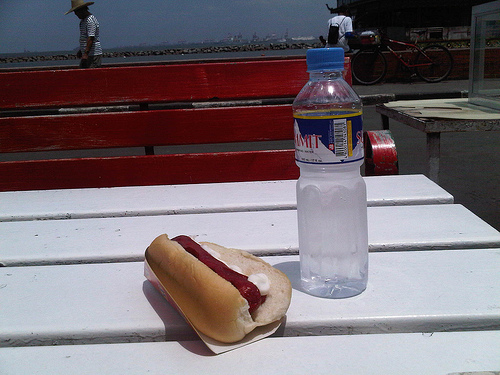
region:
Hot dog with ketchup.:
[140, 203, 300, 358]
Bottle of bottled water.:
[305, 39, 378, 346]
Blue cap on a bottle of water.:
[289, 36, 357, 71]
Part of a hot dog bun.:
[136, 245, 243, 371]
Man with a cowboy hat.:
[39, 0, 111, 70]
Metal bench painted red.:
[35, 50, 420, 233]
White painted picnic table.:
[12, 159, 480, 371]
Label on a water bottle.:
[279, 78, 374, 186]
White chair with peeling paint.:
[388, 7, 498, 188]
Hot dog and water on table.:
[176, 182, 389, 342]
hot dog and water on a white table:
[133, 8, 410, 371]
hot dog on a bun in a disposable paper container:
[117, 224, 297, 353]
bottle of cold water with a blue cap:
[290, 26, 383, 313]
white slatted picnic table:
[7, 188, 119, 373]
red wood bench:
[10, 72, 268, 182]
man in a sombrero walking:
[57, 1, 119, 71]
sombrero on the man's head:
[62, 0, 104, 19]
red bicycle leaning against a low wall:
[350, 16, 465, 86]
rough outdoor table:
[385, 86, 499, 173]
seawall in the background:
[138, 16, 308, 55]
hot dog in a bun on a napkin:
[115, 223, 307, 369]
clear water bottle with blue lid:
[280, 36, 391, 298]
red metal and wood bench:
[2, 55, 382, 195]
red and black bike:
[355, 24, 459, 98]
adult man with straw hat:
[55, 2, 110, 65]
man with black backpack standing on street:
[327, 2, 392, 59]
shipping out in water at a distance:
[180, 20, 327, 53]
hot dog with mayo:
[156, 228, 281, 315]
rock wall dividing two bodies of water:
[116, 36, 306, 59]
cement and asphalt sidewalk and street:
[375, 81, 484, 155]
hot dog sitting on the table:
[130, 218, 296, 361]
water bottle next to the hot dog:
[282, 39, 373, 309]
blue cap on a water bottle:
[301, 37, 352, 80]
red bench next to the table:
[8, 61, 444, 182]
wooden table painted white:
[3, 171, 492, 365]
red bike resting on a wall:
[346, 26, 453, 88]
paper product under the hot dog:
[195, 321, 291, 358]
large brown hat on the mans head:
[64, 1, 99, 21]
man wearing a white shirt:
[320, 6, 364, 64]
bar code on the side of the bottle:
[331, 115, 352, 165]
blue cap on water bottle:
[297, 31, 353, 298]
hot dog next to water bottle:
[138, 166, 388, 338]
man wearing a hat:
[75, 0, 101, 60]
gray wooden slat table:
[15, 187, 476, 359]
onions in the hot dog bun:
[200, 232, 270, 292]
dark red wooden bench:
[26, 57, 341, 199]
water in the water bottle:
[285, 137, 380, 312]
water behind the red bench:
[125, 30, 285, 55]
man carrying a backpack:
[327, 5, 382, 51]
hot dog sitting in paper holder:
[133, 253, 257, 355]